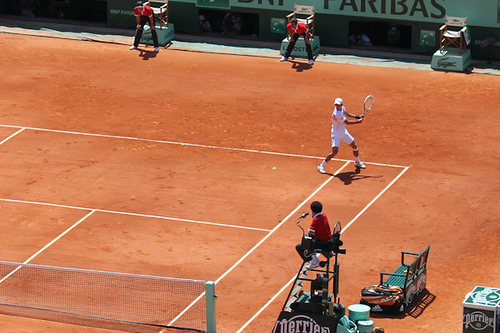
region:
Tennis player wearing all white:
[326, 91, 393, 182]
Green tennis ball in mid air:
[261, 155, 288, 185]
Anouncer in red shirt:
[294, 190, 338, 260]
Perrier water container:
[450, 278, 492, 331]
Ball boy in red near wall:
[123, 0, 164, 67]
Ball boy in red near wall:
[261, 5, 314, 80]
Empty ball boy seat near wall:
[437, 9, 463, 60]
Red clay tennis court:
[32, 63, 490, 304]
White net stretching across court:
[2, 272, 220, 327]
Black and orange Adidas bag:
[358, 280, 432, 310]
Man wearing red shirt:
[309, 217, 331, 229]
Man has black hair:
[309, 198, 326, 214]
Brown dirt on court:
[183, 165, 246, 200]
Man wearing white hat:
[334, 95, 344, 105]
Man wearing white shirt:
[334, 120, 344, 130]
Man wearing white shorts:
[333, 135, 343, 146]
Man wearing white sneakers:
[311, 159, 330, 178]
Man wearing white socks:
[352, 155, 362, 163]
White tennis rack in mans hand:
[361, 91, 376, 114]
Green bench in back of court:
[386, 243, 416, 285]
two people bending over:
[120, 4, 325, 71]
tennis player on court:
[310, 91, 386, 180]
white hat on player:
[327, 90, 349, 116]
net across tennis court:
[68, 260, 224, 325]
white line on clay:
[119, 124, 218, 157]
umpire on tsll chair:
[289, 198, 343, 280]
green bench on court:
[373, 239, 434, 302]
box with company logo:
[457, 272, 494, 331]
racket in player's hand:
[357, 90, 379, 127]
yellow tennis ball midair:
[259, 154, 290, 184]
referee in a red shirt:
[276, 11, 320, 68]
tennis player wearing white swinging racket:
[308, 82, 386, 176]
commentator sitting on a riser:
[286, 177, 338, 314]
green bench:
[363, 231, 436, 311]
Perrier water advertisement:
[453, 280, 498, 332]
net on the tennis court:
[0, 247, 220, 329]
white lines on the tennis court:
[36, 157, 273, 258]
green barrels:
[341, 297, 383, 330]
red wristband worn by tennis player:
[351, 116, 361, 124]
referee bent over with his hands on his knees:
[125, 0, 162, 56]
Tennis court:
[45, 135, 257, 257]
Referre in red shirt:
[300, 203, 340, 247]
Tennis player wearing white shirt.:
[328, 104, 358, 144]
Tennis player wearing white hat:
[333, 93, 348, 105]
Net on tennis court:
[22, 263, 115, 302]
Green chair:
[391, 255, 426, 286]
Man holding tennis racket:
[360, 86, 382, 122]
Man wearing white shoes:
[307, 156, 334, 176]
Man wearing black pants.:
[133, 17, 160, 44]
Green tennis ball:
[264, 159, 288, 176]